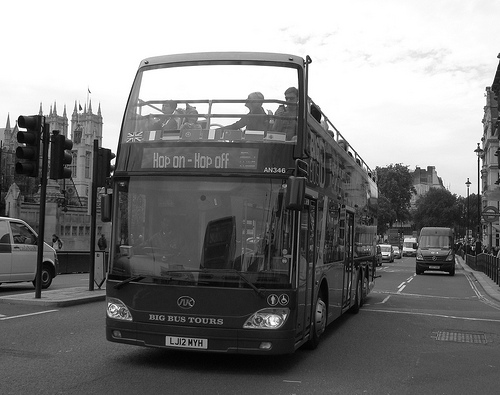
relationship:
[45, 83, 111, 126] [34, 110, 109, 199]
spires on building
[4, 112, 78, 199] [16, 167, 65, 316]
traffic lights on pole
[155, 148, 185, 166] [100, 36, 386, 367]
hop on on bus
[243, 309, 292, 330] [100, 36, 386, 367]
head light of bus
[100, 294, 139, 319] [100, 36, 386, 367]
head light of bus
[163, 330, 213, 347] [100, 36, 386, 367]
license plate of bus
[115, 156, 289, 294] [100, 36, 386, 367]
front windshield of bus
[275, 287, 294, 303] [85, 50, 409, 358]
handicap sign on bus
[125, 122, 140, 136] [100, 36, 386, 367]
british flag on bus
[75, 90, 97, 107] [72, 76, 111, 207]
flag on top tower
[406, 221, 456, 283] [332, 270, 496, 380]
van driving on road